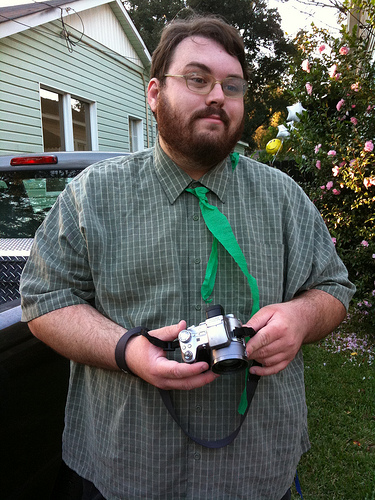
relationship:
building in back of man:
[0, 0, 250, 156] [18, 20, 356, 497]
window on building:
[34, 81, 98, 152] [3, 25, 111, 157]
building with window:
[3, 25, 111, 157] [34, 81, 98, 152]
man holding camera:
[18, 20, 356, 497] [112, 304, 264, 449]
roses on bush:
[299, 69, 345, 142] [119, 0, 375, 331]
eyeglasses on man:
[158, 72, 248, 99] [18, 20, 356, 497]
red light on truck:
[9, 153, 59, 166] [0, 151, 133, 421]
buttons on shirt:
[172, 238, 216, 303] [36, 144, 345, 465]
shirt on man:
[36, 144, 345, 465] [18, 20, 356, 497]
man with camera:
[18, 20, 356, 497] [175, 302, 248, 375]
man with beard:
[18, 20, 356, 497] [153, 82, 244, 165]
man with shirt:
[19, 8, 357, 500] [89, 168, 294, 350]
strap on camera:
[113, 324, 261, 449] [175, 302, 248, 375]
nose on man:
[203, 82, 226, 106] [19, 8, 357, 500]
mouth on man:
[196, 114, 222, 123] [19, 8, 357, 500]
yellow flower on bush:
[264, 138, 283, 156] [270, 33, 372, 253]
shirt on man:
[19, 135, 357, 500] [18, 20, 356, 497]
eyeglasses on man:
[162, 68, 249, 99] [18, 20, 356, 497]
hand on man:
[233, 309, 328, 370] [72, 29, 308, 326]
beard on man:
[136, 85, 276, 178] [49, 43, 365, 350]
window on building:
[34, 80, 79, 163] [0, 0, 250, 156]